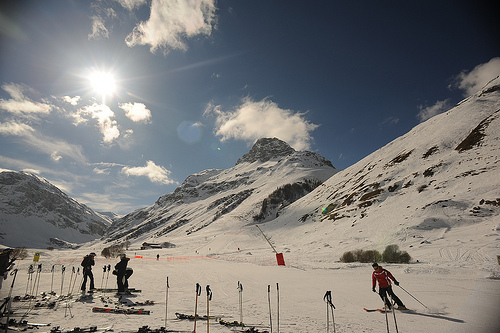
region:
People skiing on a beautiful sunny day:
[40, 222, 438, 309]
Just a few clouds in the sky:
[17, 1, 229, 158]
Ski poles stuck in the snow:
[156, 277, 298, 320]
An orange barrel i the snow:
[268, 245, 292, 269]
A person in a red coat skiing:
[351, 249, 410, 317]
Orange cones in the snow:
[139, 244, 207, 265]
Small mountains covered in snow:
[20, 121, 456, 208]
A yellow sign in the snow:
[29, 249, 41, 264]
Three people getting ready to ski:
[63, 245, 153, 290]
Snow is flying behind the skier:
[408, 302, 445, 320]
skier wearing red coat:
[358, 257, 423, 313]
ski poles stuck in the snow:
[8, 257, 403, 328]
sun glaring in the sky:
[78, 63, 124, 98]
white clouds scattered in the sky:
[9, 14, 306, 179]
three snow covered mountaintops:
[8, 79, 499, 249]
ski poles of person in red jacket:
[368, 283, 424, 308]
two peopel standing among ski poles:
[75, 245, 135, 292]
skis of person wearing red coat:
[358, 305, 392, 320]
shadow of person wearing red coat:
[407, 309, 473, 330]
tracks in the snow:
[69, 277, 334, 329]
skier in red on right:
[358, 259, 430, 316]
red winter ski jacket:
[369, 266, 399, 299]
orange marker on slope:
[270, 249, 290, 269]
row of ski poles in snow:
[5, 262, 415, 332]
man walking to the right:
[77, 251, 102, 294]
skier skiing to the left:
[362, 262, 425, 316]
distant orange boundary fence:
[129, 243, 231, 268]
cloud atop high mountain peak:
[197, 95, 319, 174]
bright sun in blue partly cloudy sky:
[59, 50, 151, 126]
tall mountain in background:
[93, 130, 340, 260]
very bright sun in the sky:
[73, 60, 124, 100]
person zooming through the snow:
[363, 254, 450, 320]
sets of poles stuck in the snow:
[160, 273, 406, 332]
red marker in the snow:
[272, 248, 290, 270]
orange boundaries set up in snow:
[111, 241, 211, 265]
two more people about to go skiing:
[77, 249, 134, 296]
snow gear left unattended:
[1, 264, 346, 331]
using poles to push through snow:
[364, 258, 446, 322]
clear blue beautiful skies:
[4, 2, 491, 222]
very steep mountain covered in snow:
[111, 135, 325, 235]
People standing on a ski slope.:
[66, 247, 428, 324]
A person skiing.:
[356, 256, 468, 328]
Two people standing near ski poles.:
[74, 247, 135, 299]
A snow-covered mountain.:
[90, 128, 337, 257]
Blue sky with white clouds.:
[4, 4, 486, 196]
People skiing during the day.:
[4, 4, 496, 323]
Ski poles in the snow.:
[159, 275, 349, 330]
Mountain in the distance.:
[5, 164, 110, 246]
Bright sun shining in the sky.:
[60, 52, 142, 112]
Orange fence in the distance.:
[132, 251, 212, 262]